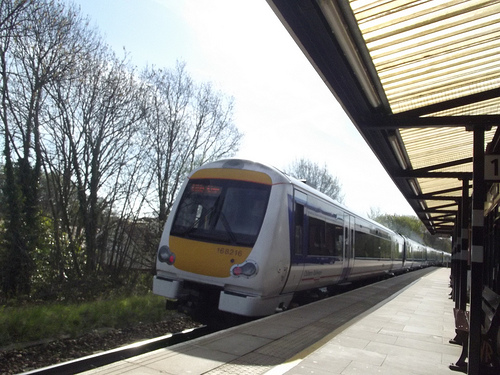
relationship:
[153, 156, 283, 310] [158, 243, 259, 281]
train is yellow train white train has headlights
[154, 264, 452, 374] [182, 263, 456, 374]
tiles are brick tile on platform platform by train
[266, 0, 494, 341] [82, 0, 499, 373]
roof is plastic roof of depot depot for train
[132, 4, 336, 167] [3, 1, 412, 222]
cloud is white cloud in sky sky is blue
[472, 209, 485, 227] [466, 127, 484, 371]
marking is white marking on post post is metal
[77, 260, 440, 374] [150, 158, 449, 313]
walkway beside train walkway white train beside walkway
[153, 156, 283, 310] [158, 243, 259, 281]
train has a front front has lights train has lights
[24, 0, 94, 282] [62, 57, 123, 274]
tree is tall tree straight tree has no leaves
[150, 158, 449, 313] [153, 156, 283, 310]
train is modern train streamlined train is yellow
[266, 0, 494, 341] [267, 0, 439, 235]
roof is tan roof ridged roof has dark edge